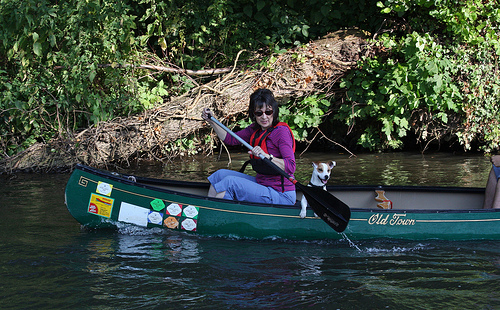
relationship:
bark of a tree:
[94, 120, 134, 156] [6, 25, 371, 169]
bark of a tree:
[172, 27, 357, 88] [2, 13, 410, 173]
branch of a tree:
[36, 55, 240, 100] [342, 8, 489, 127]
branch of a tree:
[360, 51, 477, 148] [342, 8, 489, 127]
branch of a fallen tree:
[133, 55, 240, 82] [0, 0, 499, 173]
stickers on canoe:
[84, 181, 206, 241] [71, 165, 498, 252]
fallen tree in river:
[10, 30, 498, 166] [0, 150, 497, 308]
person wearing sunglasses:
[201, 88, 296, 206] [252, 109, 277, 115]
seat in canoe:
[369, 182, 394, 212] [71, 165, 498, 252]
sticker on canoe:
[85, 192, 112, 217] [62, 162, 498, 241]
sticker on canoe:
[147, 198, 200, 232] [65, 155, 497, 252]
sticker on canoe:
[147, 198, 200, 232] [62, 162, 498, 241]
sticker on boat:
[147, 198, 200, 232] [64, 156, 500, 243]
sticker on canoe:
[147, 198, 200, 232] [86, 175, 481, 235]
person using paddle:
[201, 88, 296, 206] [202, 107, 351, 234]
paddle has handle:
[202, 107, 351, 234] [200, 105, 266, 161]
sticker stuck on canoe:
[147, 198, 200, 232] [81, 160, 488, 249]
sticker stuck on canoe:
[146, 211, 163, 225] [81, 160, 488, 249]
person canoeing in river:
[206, 89, 296, 208] [0, 150, 497, 308]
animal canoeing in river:
[298, 161, 339, 218] [0, 150, 497, 308]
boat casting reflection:
[64, 156, 500, 243] [88, 235, 324, 307]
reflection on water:
[88, 235, 324, 307] [0, 154, 497, 308]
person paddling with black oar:
[201, 88, 296, 206] [290, 179, 349, 236]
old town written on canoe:
[365, 211, 415, 229] [71, 165, 498, 252]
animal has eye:
[299, 160, 337, 218] [312, 167, 324, 177]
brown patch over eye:
[313, 161, 324, 174] [312, 167, 324, 177]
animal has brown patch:
[299, 160, 337, 218] [313, 161, 324, 174]